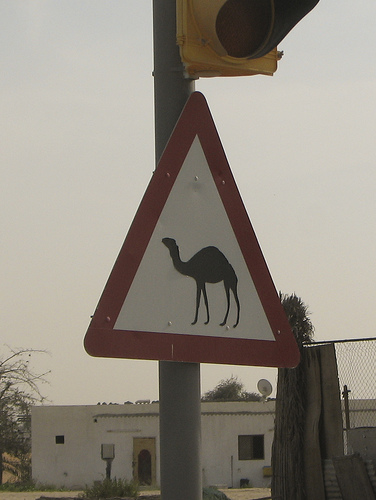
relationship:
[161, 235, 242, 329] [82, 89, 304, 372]
camel on a sign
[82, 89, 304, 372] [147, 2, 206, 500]
sign attached to a pole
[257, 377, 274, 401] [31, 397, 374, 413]
satellite on roof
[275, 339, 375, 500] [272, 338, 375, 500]
wood standing by fence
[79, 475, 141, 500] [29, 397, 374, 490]
bushes are in front of building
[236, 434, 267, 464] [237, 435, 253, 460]
window has a curtain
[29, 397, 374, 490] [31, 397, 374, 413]
building has a flat roof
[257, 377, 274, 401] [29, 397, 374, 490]
satellite on top of building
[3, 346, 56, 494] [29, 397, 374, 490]
tree standing beside a building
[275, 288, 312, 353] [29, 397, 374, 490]
tree above building